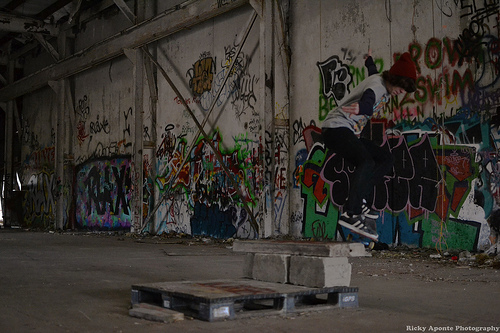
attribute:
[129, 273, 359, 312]
pallet — wood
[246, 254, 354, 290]
cinder block — white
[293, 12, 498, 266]
graffiti — black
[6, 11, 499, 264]
wall — wood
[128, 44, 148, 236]
beam — concrete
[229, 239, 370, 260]
slab — concrete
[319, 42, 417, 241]
skateboarder — jumping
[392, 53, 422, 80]
cap — red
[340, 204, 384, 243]
shoes — gray, white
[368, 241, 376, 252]
wheel — white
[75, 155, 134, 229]
graffiti — colorful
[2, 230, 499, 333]
ground — dusty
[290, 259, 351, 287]
cinder block — large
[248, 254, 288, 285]
cinder block — large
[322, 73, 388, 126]
shirt — grey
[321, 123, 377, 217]
pants — black